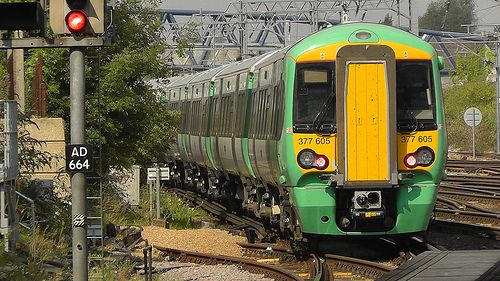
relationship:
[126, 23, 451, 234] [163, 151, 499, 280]
train on tracks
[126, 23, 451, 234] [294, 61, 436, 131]
train has windshield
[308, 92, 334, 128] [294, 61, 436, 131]
wiper on windshield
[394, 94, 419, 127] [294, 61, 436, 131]
wiper on windshield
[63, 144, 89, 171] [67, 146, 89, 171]
sign has writing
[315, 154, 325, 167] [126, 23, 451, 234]
headlight on train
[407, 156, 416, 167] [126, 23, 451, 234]
headlight on train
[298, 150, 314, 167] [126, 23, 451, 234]
headlight on train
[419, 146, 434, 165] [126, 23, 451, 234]
headlight on train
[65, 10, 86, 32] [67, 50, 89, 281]
light on pole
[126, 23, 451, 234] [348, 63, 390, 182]
train has door